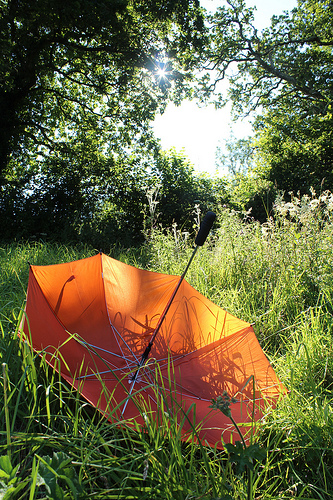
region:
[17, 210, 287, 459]
orange umbrella in grass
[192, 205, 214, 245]
long handle for umbrella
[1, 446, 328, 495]
nice green grass blades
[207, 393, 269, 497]
weeds in green grass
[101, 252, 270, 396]
sun shining on umbrella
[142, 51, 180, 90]
bright light shining through trees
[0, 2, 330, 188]
trees with green leaves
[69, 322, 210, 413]
support wires for umbrella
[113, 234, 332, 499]
tall grass in picture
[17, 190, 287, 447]
one upside down umbrella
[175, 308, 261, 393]
silhouette of grass on umbrella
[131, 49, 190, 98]
sunlight shinning through trees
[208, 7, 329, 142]
tree branch with green foliage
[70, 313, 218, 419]
spokes on underside of an umbrella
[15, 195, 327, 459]
upside down orange umbrella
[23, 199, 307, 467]
open umbrella in field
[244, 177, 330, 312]
tall green foliage in field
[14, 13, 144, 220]
tree branches with green leaves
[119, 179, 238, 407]
handle of open umbrella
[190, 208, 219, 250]
the handle is plastic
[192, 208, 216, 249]
the handle is black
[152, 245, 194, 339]
the pole is metal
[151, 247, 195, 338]
the pole is silver in color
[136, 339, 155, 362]
the plastic is what holds the umbrella open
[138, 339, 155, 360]
the piece is black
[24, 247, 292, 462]
the umbrella is open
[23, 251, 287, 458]
the umbrella is orange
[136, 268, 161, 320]
a shadow is on the umbrella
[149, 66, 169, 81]
the sun is shining through the trees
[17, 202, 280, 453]
open orange umbrella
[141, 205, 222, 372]
black handle of orange umbrella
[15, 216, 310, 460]
orange umbrella on the ground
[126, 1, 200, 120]
sun shining through green trees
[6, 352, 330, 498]
high green grass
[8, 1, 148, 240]
overgrown green trees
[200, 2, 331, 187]
tall tree with leaves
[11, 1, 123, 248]
tall tree with many leaves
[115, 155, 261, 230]
short trees with many leaves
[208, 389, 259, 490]
wild flower mixed in green grass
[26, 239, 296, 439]
The umbrella is orange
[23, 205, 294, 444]
The umbrella is upside down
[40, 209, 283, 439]
The umbrella is open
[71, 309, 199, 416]
The umbrella has metal bars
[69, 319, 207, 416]
Thin metal bars on umbrella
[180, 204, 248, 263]
The umbrella has a black handle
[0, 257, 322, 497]
Tall thin green grass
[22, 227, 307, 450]
The umbrella is in the grass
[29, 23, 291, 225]
There are trees by the grass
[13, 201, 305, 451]
The grass is covering the umbrella